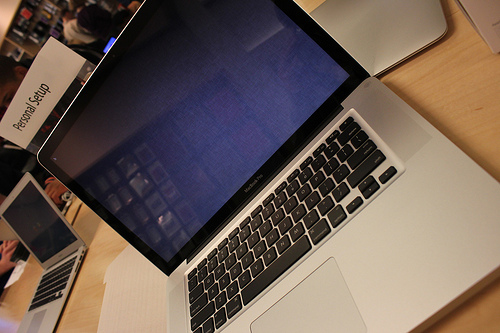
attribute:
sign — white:
[0, 35, 88, 148]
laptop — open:
[5, 162, 89, 331]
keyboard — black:
[164, 103, 369, 331]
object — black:
[9, 241, 29, 261]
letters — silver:
[237, 169, 262, 197]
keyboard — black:
[185, 116, 399, 325]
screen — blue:
[10, 3, 366, 270]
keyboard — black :
[176, 104, 391, 329]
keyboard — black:
[132, 123, 472, 325]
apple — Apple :
[1, 172, 89, 331]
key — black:
[308, 220, 329, 240]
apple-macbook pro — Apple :
[37, 3, 498, 331]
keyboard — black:
[170, 116, 412, 331]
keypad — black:
[145, 110, 399, 331]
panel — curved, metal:
[312, 0, 459, 75]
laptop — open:
[37, 4, 494, 332]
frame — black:
[32, 1, 370, 273]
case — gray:
[170, 77, 493, 323]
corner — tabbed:
[99, 260, 122, 284]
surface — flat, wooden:
[4, 0, 496, 330]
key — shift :
[180, 300, 220, 326]